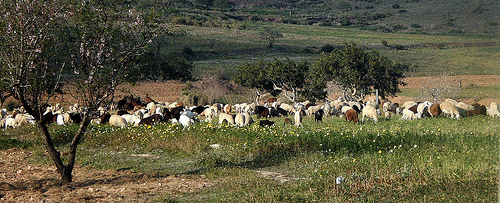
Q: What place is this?
A: It is a field.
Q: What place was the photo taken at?
A: It was taken at the field.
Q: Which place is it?
A: It is a field.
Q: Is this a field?
A: Yes, it is a field.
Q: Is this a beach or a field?
A: It is a field.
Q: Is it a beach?
A: No, it is a field.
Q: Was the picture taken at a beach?
A: No, the picture was taken in a field.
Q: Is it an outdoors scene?
A: Yes, it is outdoors.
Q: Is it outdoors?
A: Yes, it is outdoors.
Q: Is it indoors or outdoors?
A: It is outdoors.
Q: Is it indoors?
A: No, it is outdoors.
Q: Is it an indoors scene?
A: No, it is outdoors.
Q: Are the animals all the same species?
A: Yes, all the animals are sheep.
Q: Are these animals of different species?
A: No, all the animals are sheep.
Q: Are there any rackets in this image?
A: No, there are no rackets.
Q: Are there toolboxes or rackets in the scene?
A: No, there are no rackets or toolboxes.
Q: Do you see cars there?
A: No, there are no cars.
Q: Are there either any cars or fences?
A: No, there are no cars or fences.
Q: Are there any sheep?
A: Yes, there is a sheep.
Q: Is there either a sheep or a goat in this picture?
A: Yes, there is a sheep.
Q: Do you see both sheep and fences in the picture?
A: No, there is a sheep but no fences.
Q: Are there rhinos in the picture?
A: No, there are no rhinos.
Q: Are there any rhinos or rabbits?
A: No, there are no rhinos or rabbits.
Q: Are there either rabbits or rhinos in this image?
A: No, there are no rhinos or rabbits.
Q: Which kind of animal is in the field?
A: The animal is a sheep.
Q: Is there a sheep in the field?
A: Yes, there is a sheep in the field.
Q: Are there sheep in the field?
A: Yes, there is a sheep in the field.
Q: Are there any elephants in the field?
A: No, there is a sheep in the field.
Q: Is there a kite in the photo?
A: No, there are no kites.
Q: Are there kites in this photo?
A: No, there are no kites.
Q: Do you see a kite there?
A: No, there are no kites.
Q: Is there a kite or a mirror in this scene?
A: No, there are no kites or mirrors.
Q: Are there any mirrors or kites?
A: No, there are no kites or mirrors.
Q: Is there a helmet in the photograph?
A: No, there are no helmets.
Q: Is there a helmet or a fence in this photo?
A: No, there are no helmets or fences.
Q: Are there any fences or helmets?
A: No, there are no helmets or fences.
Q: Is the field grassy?
A: Yes, the field is grassy.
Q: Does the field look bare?
A: No, the field is grassy.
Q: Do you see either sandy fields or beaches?
A: No, there is a field but it is grassy.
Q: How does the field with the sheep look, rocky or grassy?
A: The field is grassy.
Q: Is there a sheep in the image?
A: Yes, there is a sheep.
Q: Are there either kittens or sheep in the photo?
A: Yes, there is a sheep.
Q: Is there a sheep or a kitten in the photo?
A: Yes, there is a sheep.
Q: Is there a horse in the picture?
A: No, there are no horses.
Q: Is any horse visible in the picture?
A: No, there are no horses.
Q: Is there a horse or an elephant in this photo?
A: No, there are no horses or elephants.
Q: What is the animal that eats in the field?
A: The animal is a sheep.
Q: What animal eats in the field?
A: The animal is a sheep.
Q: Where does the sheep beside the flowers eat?
A: The sheep eats in the field.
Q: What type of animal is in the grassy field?
A: The animal is a sheep.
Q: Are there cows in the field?
A: No, there is a sheep in the field.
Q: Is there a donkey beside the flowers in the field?
A: No, there is a sheep beside the flowers.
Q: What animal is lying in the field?
A: The animal is a sheep.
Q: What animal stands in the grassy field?
A: The animal is a sheep.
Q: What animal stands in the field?
A: The animal is a sheep.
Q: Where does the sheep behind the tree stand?
A: The sheep stands in the field.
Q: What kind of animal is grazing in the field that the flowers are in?
A: The animal is a sheep.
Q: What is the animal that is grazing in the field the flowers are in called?
A: The animal is a sheep.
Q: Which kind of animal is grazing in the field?
A: The animal is a sheep.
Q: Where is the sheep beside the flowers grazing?
A: The sheep is grazing in the field.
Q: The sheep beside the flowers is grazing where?
A: The sheep is grazing in the field.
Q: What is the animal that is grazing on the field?
A: The animal is a sheep.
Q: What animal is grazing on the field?
A: The animal is a sheep.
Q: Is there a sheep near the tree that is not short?
A: Yes, there is a sheep near the tree.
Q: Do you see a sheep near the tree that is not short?
A: Yes, there is a sheep near the tree.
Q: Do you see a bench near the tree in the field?
A: No, there is a sheep near the tree.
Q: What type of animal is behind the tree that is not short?
A: The animal is a sheep.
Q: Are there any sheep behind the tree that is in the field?
A: Yes, there is a sheep behind the tree.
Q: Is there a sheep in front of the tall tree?
A: No, the sheep is behind the tree.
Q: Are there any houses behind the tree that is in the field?
A: No, there is a sheep behind the tree.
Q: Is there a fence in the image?
A: No, there are no fences.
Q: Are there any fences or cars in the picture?
A: No, there are no fences or cars.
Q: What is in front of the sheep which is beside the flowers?
A: The tree is in front of the sheep.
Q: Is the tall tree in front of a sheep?
A: Yes, the tree is in front of a sheep.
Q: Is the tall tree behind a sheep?
A: No, the tree is in front of a sheep.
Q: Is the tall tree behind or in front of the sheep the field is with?
A: The tree is in front of the sheep.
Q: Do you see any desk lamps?
A: No, there are no desk lamps.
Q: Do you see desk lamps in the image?
A: No, there are no desk lamps.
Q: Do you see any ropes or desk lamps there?
A: No, there are no desk lamps or ropes.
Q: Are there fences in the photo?
A: No, there are no fences.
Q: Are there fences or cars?
A: No, there are no fences or cars.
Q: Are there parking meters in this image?
A: No, there are no parking meters.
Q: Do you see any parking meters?
A: No, there are no parking meters.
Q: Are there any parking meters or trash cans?
A: No, there are no parking meters or trash cans.